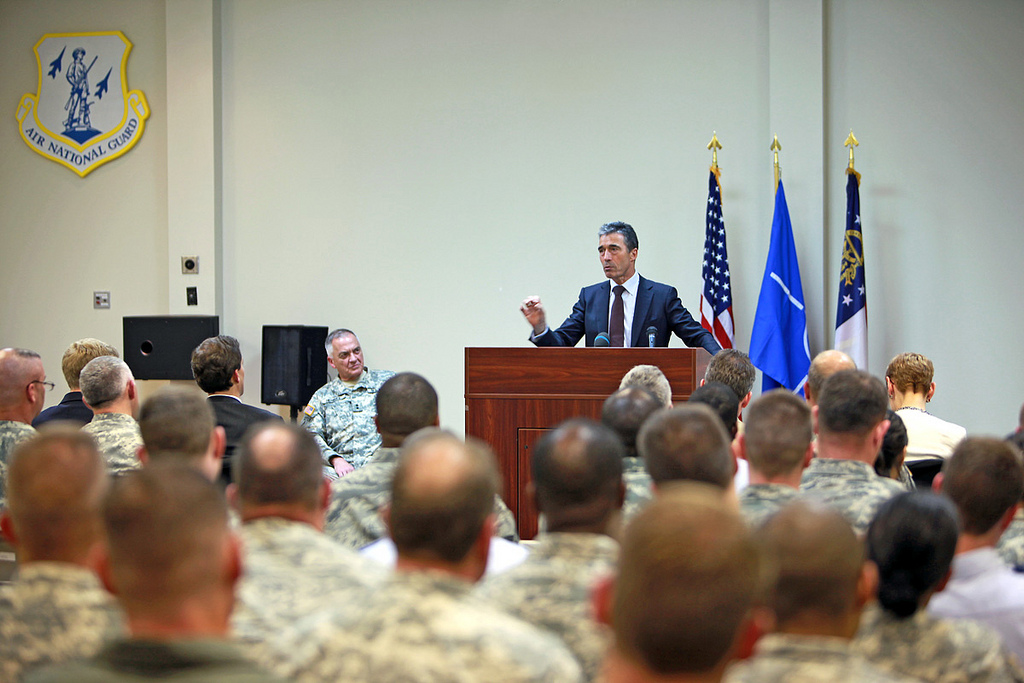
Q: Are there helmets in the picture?
A: No, there are no helmets.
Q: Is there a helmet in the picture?
A: No, there are no helmets.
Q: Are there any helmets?
A: No, there are no helmets.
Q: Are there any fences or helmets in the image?
A: No, there are no helmets or fences.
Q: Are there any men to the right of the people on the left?
A: Yes, there is a man to the right of the people.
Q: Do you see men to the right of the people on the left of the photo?
A: Yes, there is a man to the right of the people.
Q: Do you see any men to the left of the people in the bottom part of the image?
A: No, the man is to the right of the people.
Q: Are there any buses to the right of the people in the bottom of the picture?
A: No, there is a man to the right of the people.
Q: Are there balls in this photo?
A: No, there are no balls.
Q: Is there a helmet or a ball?
A: No, there are no balls or helmets.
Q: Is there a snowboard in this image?
A: No, there are no snowboards.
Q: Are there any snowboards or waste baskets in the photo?
A: No, there are no snowboards or waste baskets.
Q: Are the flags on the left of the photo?
A: No, the flags are on the right of the image.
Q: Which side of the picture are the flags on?
A: The flags are on the right of the image.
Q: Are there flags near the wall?
A: Yes, there are flags near the wall.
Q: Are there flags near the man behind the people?
A: Yes, there are flags near the man.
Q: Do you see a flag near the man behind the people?
A: Yes, there are flags near the man.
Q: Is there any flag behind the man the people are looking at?
A: Yes, there are flags behind the man.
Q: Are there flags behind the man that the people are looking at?
A: Yes, there are flags behind the man.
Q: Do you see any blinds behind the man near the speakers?
A: No, there are flags behind the man.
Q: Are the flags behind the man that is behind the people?
A: Yes, the flags are behind the man.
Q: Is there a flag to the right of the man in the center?
A: Yes, there are flags to the right of the man.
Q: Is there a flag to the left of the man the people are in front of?
A: No, the flags are to the right of the man.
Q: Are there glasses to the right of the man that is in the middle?
A: No, there are flags to the right of the man.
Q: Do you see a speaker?
A: Yes, there are speakers.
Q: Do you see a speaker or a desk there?
A: Yes, there are speakers.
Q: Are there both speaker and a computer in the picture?
A: No, there are speakers but no computers.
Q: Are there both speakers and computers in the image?
A: No, there are speakers but no computers.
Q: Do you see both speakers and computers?
A: No, there are speakers but no computers.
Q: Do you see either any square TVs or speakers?
A: Yes, there are square speakers.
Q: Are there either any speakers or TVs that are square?
A: Yes, the speakers are square.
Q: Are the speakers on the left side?
A: Yes, the speakers are on the left of the image.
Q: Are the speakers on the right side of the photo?
A: No, the speakers are on the left of the image.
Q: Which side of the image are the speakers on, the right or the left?
A: The speakers are on the left of the image.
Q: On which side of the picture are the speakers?
A: The speakers are on the left of the image.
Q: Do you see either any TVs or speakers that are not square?
A: No, there are speakers but they are square.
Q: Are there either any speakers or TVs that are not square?
A: No, there are speakers but they are square.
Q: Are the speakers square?
A: Yes, the speakers are square.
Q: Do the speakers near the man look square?
A: Yes, the speakers are square.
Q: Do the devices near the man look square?
A: Yes, the speakers are square.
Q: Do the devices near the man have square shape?
A: Yes, the speakers are square.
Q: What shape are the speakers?
A: The speakers are square.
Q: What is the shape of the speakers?
A: The speakers are square.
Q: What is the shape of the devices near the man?
A: The speakers are square.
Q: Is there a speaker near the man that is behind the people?
A: Yes, there are speakers near the man.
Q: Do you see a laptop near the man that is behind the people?
A: No, there are speakers near the man.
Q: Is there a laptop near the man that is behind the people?
A: No, there are speakers near the man.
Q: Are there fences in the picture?
A: No, there are no fences.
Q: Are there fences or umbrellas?
A: No, there are no fences or umbrellas.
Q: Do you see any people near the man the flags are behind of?
A: Yes, there are people near the man.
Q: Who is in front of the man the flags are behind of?
A: The people are in front of the man.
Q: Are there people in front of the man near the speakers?
A: Yes, there are people in front of the man.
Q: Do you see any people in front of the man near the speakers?
A: Yes, there are people in front of the man.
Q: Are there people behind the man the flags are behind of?
A: No, the people are in front of the man.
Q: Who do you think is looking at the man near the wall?
A: The people are looking at the man.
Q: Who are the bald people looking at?
A: The people are looking at the man.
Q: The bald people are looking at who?
A: The people are looking at the man.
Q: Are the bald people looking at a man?
A: Yes, the people are looking at a man.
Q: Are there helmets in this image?
A: No, there are no helmets.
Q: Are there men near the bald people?
A: Yes, there is a man near the people.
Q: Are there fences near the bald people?
A: No, there is a man near the people.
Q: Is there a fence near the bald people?
A: No, there is a man near the people.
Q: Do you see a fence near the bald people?
A: No, there is a man near the people.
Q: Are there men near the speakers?
A: Yes, there is a man near the speakers.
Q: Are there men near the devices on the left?
A: Yes, there is a man near the speakers.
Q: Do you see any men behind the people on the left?
A: Yes, there is a man behind the people.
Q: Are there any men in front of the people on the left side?
A: No, the man is behind the people.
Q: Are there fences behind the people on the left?
A: No, there is a man behind the people.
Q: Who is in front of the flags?
A: The man is in front of the flags.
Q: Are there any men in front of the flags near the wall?
A: Yes, there is a man in front of the flags.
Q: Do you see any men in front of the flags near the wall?
A: Yes, there is a man in front of the flags.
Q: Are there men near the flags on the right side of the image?
A: Yes, there is a man near the flags.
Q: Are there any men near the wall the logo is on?
A: Yes, there is a man near the wall.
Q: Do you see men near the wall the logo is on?
A: Yes, there is a man near the wall.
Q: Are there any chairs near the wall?
A: No, there is a man near the wall.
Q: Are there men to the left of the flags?
A: Yes, there is a man to the left of the flags.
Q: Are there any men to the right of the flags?
A: No, the man is to the left of the flags.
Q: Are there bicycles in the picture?
A: No, there are no bicycles.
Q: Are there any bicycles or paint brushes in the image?
A: No, there are no bicycles or paint brushes.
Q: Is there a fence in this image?
A: No, there are no fences.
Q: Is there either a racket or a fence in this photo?
A: No, there are no fences or rackets.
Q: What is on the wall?
A: The logo is on the wall.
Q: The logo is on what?
A: The logo is on the wall.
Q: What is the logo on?
A: The logo is on the wall.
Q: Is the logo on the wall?
A: Yes, the logo is on the wall.